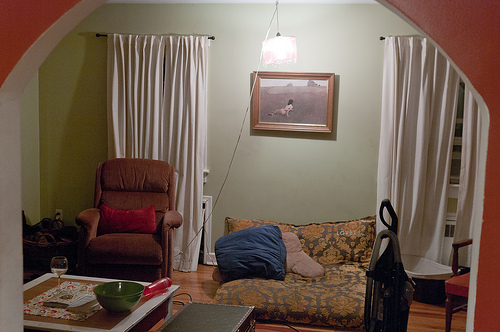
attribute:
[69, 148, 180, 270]
recliner — brown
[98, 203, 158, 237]
pillow — red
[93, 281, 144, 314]
bowl — green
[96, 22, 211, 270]
curtains — white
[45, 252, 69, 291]
wine glass — empty